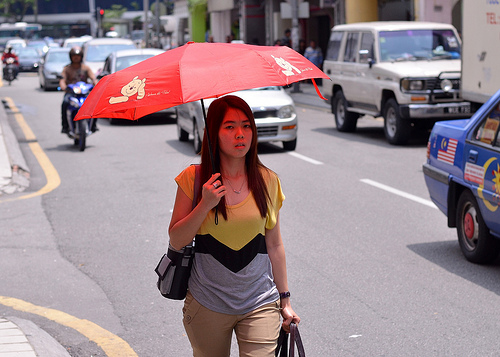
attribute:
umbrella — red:
[62, 25, 333, 144]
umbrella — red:
[68, 20, 358, 161]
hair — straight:
[204, 95, 225, 215]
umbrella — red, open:
[68, 30, 326, 212]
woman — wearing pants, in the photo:
[156, 94, 303, 354]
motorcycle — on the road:
[56, 47, 97, 151]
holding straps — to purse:
[277, 317, 309, 354]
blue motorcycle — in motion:
[56, 80, 95, 152]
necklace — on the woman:
[222, 174, 250, 196]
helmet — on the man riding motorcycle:
[68, 44, 83, 66]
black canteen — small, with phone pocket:
[155, 240, 196, 300]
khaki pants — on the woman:
[182, 290, 278, 348]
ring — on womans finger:
[211, 180, 217, 187]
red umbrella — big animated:
[70, 36, 331, 127]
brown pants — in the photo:
[180, 294, 284, 354]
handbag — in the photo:
[277, 318, 312, 354]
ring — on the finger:
[212, 180, 220, 187]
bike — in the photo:
[56, 80, 95, 151]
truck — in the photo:
[319, 20, 469, 146]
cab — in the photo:
[425, 81, 485, 266]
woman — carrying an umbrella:
[146, 95, 317, 353]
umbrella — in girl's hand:
[71, 39, 332, 121]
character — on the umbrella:
[108, 72, 147, 105]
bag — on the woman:
[153, 244, 195, 297]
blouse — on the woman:
[172, 162, 287, 313]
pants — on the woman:
[180, 294, 281, 354]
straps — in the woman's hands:
[276, 319, 309, 355]